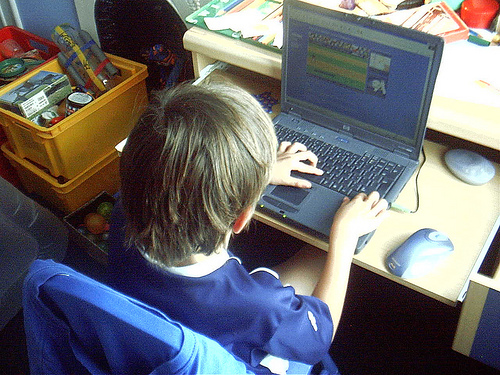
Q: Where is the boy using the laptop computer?
A: Desk.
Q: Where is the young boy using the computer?
A: Bedroom.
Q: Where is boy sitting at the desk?
A: Chair.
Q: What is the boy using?
A: Laptop keyboard.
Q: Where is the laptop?
A: On a white desk.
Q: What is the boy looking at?
A: Laptop screen.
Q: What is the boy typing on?
A: Black keyboard.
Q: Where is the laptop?
A: Open on a desk.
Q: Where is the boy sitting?
A: At a computer desk.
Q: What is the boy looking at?
A: Laptop computer screen.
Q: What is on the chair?
A: A Blue t-shirt.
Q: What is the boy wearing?
A: A two tone shirt.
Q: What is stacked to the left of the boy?
A: Two yellow bins.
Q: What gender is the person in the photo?
A: Male.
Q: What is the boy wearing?
A: A jersey.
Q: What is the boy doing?
A: Sitting at a desk.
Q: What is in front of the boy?
A: A laptop.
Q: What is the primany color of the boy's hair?
A: Brown.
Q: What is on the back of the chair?
A: A shirt.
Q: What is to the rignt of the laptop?
A: A mouse.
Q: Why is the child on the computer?
A: He is playing a video game.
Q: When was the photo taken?
A: Daytime.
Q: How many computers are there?
A: One.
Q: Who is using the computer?
A: The child.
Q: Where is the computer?
A: On a desk.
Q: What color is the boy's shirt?
A: Blue.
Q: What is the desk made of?
A: Wood.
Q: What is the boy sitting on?
A: A chair.